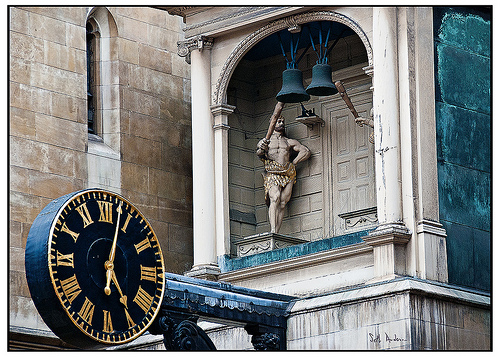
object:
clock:
[25, 187, 165, 346]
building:
[10, 9, 490, 351]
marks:
[431, 6, 492, 289]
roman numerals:
[45, 177, 166, 343]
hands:
[104, 200, 129, 307]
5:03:
[104, 197, 139, 329]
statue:
[255, 100, 312, 233]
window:
[82, 17, 103, 143]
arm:
[287, 139, 311, 167]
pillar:
[369, 6, 408, 235]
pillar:
[177, 35, 223, 279]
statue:
[334, 78, 374, 145]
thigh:
[266, 184, 281, 200]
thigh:
[280, 185, 293, 203]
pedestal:
[222, 232, 309, 259]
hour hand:
[106, 261, 129, 309]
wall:
[10, 6, 500, 335]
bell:
[276, 69, 311, 103]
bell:
[305, 64, 338, 97]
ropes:
[280, 26, 349, 67]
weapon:
[260, 101, 285, 158]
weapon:
[335, 78, 362, 129]